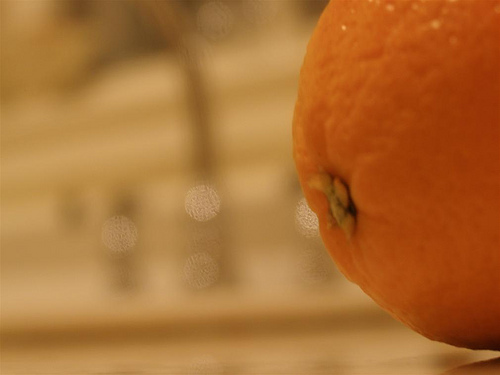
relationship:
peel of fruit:
[290, 0, 498, 352] [269, 1, 494, 372]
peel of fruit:
[290, 0, 498, 352] [288, 0, 500, 354]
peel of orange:
[290, 0, 498, 352] [431, 160, 481, 213]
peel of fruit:
[290, 0, 498, 352] [291, 0, 498, 362]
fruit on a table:
[288, 0, 500, 354] [6, 295, 498, 372]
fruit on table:
[288, 0, 500, 354] [2, 322, 497, 373]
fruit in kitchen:
[288, 0, 500, 354] [9, 5, 494, 368]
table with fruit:
[6, 295, 498, 372] [288, 0, 500, 354]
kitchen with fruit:
[9, 5, 494, 368] [288, 0, 500, 354]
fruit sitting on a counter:
[288, 0, 500, 354] [1, 287, 498, 374]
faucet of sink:
[57, 19, 239, 301] [81, 0, 331, 312]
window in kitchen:
[0, 2, 315, 52] [9, 5, 494, 368]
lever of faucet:
[216, 155, 338, 293] [53, 6, 246, 305]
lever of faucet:
[12, 161, 152, 286] [53, 6, 246, 305]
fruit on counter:
[288, 3, 482, 371] [46, 269, 426, 373]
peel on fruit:
[290, 0, 498, 352] [296, 8, 479, 267]